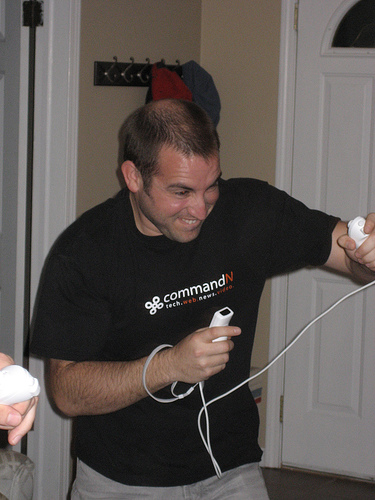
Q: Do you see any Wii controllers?
A: Yes, there is a Wii controller.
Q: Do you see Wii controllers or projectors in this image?
A: Yes, there is a Wii controller.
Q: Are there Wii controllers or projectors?
A: Yes, there is a Wii controller.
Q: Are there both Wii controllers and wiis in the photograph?
A: Yes, there are both a Wii controller and a wii.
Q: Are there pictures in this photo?
A: No, there are no pictures.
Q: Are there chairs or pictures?
A: No, there are no pictures or chairs.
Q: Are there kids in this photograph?
A: No, there are no kids.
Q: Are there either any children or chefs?
A: No, there are no children or chefs.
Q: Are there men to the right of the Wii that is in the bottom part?
A: Yes, there is a man to the right of the Wii.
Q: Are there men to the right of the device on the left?
A: Yes, there is a man to the right of the Wii.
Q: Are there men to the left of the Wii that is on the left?
A: No, the man is to the right of the Wii.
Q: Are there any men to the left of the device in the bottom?
A: No, the man is to the right of the Wii.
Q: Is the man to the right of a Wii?
A: Yes, the man is to the right of a Wii.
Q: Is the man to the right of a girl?
A: No, the man is to the right of a Wii.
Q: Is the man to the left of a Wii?
A: No, the man is to the right of a Wii.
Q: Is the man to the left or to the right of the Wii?
A: The man is to the right of the Wii.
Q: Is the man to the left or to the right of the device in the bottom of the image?
A: The man is to the right of the Wii.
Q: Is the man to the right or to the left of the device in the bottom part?
A: The man is to the right of the Wii.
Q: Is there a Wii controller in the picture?
A: Yes, there is a Wii controller.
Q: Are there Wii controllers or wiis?
A: Yes, there is a Wii controller.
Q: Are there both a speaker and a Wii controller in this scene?
A: No, there is a Wii controller but no speakers.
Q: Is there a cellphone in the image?
A: No, there are no cell phones.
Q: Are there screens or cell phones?
A: No, there are no cell phones or screens.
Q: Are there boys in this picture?
A: No, there are no boys.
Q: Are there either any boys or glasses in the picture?
A: No, there are no boys or glasses.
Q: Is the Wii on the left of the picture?
A: Yes, the Wii is on the left of the image.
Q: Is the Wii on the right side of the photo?
A: No, the Wii is on the left of the image.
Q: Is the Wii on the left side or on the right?
A: The Wii is on the left of the image.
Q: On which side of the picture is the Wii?
A: The Wii is on the left of the image.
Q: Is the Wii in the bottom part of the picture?
A: Yes, the Wii is in the bottom of the image.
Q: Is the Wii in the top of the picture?
A: No, the Wii is in the bottom of the image.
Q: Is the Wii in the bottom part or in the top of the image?
A: The Wii is in the bottom of the image.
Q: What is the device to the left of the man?
A: The device is a Wii.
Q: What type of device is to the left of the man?
A: The device is a Wii.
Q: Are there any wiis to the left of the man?
A: Yes, there is a Wii to the left of the man.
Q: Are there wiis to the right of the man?
A: No, the Wii is to the left of the man.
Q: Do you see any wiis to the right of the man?
A: No, the Wii is to the left of the man.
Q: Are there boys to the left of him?
A: No, there is a Wii to the left of the man.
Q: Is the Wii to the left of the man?
A: Yes, the Wii is to the left of the man.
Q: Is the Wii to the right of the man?
A: No, the Wii is to the left of the man.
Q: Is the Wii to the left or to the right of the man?
A: The Wii is to the left of the man.